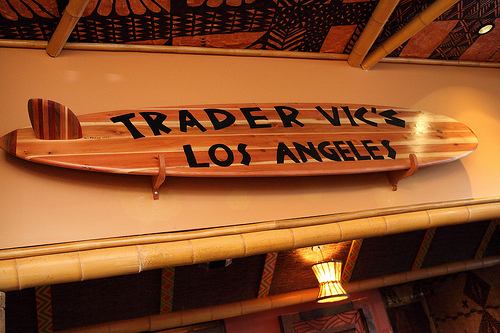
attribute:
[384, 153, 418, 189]
bracket — wood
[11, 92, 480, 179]
surfboard — wooden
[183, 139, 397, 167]
words — black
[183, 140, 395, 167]
los angeles — black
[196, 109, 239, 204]
word — black